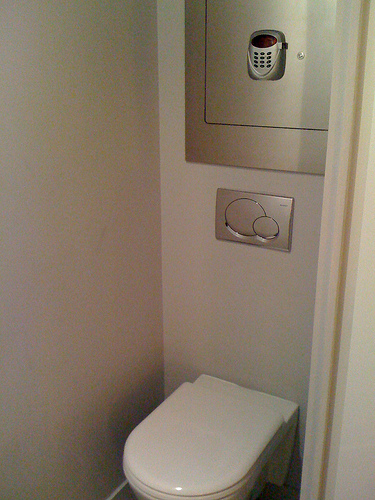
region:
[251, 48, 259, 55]
Small black and white button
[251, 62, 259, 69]
Small black and white button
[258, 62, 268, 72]
Small black and white button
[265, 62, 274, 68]
Small black and white button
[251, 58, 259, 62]
Small black and white button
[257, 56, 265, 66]
Small black and white button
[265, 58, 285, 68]
Small black and white button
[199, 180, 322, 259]
Silver plate on the wall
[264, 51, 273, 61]
Small black and white button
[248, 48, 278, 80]
Small black and white button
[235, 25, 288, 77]
keypad on a wall safe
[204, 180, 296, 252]
flush buttons for the toilet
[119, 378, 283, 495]
toilet with the lid down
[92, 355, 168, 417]
shadow on the wall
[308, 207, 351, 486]
door frame into the bathroom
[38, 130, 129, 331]
wall beside the toilet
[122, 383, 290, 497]
bathroom toilet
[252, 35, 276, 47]
digital display on the keypad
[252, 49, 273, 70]
number buttons on the keypad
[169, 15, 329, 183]
wall safe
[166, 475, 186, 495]
light reflected on a toilet lid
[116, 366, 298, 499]
closed toilet lid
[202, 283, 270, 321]
white painted wall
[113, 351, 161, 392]
shadow on a wall from the toilet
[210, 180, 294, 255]
silver buttons on the wall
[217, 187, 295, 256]
flush botton on the wall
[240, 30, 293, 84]
buttons on the wall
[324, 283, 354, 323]
shadow from the moulding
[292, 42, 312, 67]
silver circle on a silver door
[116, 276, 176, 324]
corner in a bathroom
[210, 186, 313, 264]
The buttons are silver.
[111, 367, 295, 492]
The toilet is white.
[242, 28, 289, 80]
The device is silver.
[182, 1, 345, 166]
The safe is in the wall.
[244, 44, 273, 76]
The buttons are black.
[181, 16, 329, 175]
The safe is closed.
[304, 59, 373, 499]
The curtain is white.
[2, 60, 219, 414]
The wall is white.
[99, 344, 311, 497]
The toilet is on the wall.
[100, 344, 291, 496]
The lid is closed.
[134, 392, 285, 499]
this is a toilet sink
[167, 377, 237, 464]
the top is closed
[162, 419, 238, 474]
the sink is white in color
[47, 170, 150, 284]
this is the wall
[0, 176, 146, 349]
the wall is white in color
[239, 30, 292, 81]
this is a cell phone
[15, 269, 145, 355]
the wall is cream in color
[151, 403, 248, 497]
the sink is clean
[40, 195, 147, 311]
the wall is clean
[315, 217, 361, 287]
this is the door